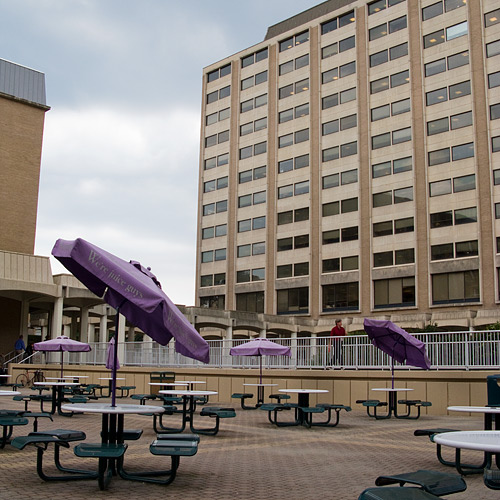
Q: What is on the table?
A: A purple patio umbrella.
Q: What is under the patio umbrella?
A: An outdoor dining table.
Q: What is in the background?
A: Building with a lot of windows.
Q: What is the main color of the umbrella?
A: Purple.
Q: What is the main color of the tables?
A: White.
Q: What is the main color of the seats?
A: Black.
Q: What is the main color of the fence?
A: White.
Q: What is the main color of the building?
A: Brown.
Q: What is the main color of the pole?
A: Black.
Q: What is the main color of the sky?
A: White.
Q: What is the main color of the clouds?
A: White.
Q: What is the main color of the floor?
A: Brown.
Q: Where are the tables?
A: On the ground.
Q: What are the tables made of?
A: Metal.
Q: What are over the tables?
A: Umbrellas.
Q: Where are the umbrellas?
A: Over the tables.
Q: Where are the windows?
A: On the building.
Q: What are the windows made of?
A: Glass.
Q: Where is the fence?
A: Around the building.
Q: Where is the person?
A: Behind the fence.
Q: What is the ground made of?
A: Bricks.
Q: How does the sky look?
A: Cloudy.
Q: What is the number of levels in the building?
A: 11.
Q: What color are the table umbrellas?
A: Purple.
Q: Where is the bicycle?
A: Next to steps on left.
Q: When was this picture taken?
A: Daytime.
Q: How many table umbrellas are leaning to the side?
A: 2.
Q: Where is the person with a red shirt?
A: Walking behind railing.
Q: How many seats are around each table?
A: 6.